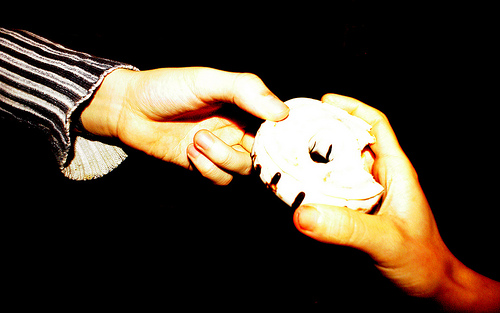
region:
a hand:
[291, 109, 409, 311]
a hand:
[380, 141, 415, 311]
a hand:
[334, 146, 373, 288]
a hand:
[358, 177, 393, 307]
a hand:
[331, 215, 369, 309]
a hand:
[336, 114, 435, 284]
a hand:
[375, 132, 452, 307]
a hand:
[364, 122, 422, 262]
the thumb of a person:
[143, 59, 295, 128]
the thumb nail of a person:
[256, 89, 293, 118]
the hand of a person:
[114, 55, 291, 195]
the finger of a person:
[193, 122, 270, 178]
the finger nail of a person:
[191, 127, 218, 153]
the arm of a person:
[0, 19, 140, 148]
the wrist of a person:
[72, 61, 150, 144]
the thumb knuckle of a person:
[226, 68, 263, 105]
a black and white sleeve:
[0, 20, 143, 186]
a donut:
[241, 84, 393, 230]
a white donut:
[251, 94, 386, 223]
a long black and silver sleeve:
[1, 24, 138, 180]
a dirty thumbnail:
[290, 199, 323, 234]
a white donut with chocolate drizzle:
[250, 95, 387, 222]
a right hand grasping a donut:
[291, 90, 498, 312]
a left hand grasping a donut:
[73, 56, 290, 186]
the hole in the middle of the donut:
[305, 133, 337, 164]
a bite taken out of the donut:
[355, 121, 387, 193]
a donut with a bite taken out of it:
[247, 92, 384, 217]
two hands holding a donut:
[1, 20, 498, 311]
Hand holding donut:
[80, 50, 292, 187]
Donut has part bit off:
[250, 85, 390, 218]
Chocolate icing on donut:
[288, 183, 305, 208]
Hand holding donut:
[293, 71, 498, 307]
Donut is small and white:
[250, 87, 381, 208]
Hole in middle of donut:
[302, 136, 337, 166]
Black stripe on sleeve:
[0, 83, 70, 140]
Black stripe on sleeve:
[0, 65, 76, 115]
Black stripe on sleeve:
[0, 30, 109, 77]